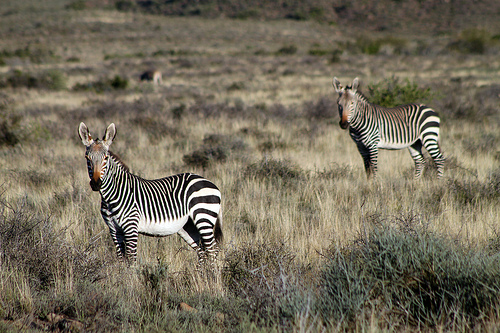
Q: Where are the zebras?
A: Standing on the grass.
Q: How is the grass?
A: Dry and yellow.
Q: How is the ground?
A: Covered with dry yellow grass and a few green bushes.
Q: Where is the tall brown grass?
A: In the field.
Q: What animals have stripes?
A: Zebras.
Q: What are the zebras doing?
A: Standing.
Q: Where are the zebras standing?
A: In the field.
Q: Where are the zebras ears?
A: On top of their heads.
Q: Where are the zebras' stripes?
A: On the zebras' bodies.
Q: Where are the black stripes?
A: On the zebras.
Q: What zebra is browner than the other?
A: The one on the right.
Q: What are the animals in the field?
A: Zebra.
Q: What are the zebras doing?
A: Standing.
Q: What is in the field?
A: Grass.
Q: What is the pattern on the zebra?
A: Stripes.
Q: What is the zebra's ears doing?
A: Standing up.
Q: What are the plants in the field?
A: Shrubs.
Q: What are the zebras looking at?
A: Camera.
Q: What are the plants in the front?
A: Weeds.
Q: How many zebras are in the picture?
A: 2.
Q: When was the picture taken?
A: Daytime.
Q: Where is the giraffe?
A: There isn't one.